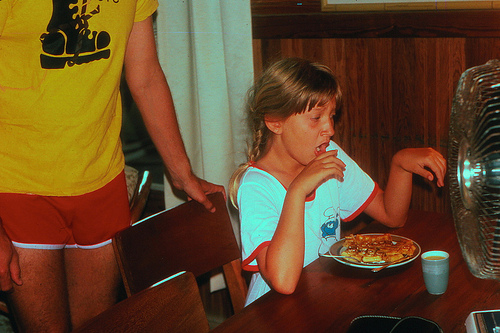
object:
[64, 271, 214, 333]
chair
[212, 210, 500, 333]
table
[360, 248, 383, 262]
waffles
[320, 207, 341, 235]
print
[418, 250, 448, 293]
cup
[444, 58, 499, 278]
fan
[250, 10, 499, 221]
wood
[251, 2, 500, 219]
wall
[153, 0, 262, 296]
curtain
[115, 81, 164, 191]
door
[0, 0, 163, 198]
shirt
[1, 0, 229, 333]
man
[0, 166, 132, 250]
shorts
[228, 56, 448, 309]
girl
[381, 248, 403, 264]
waffle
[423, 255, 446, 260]
beverage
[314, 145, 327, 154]
finger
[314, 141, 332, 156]
mouth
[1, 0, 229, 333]
someone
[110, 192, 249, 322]
chair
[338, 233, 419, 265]
meal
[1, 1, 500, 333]
room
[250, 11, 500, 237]
panel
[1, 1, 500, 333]
photo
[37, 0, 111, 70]
print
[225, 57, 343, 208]
hair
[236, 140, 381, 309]
t-shirt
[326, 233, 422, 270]
plate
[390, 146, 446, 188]
hand